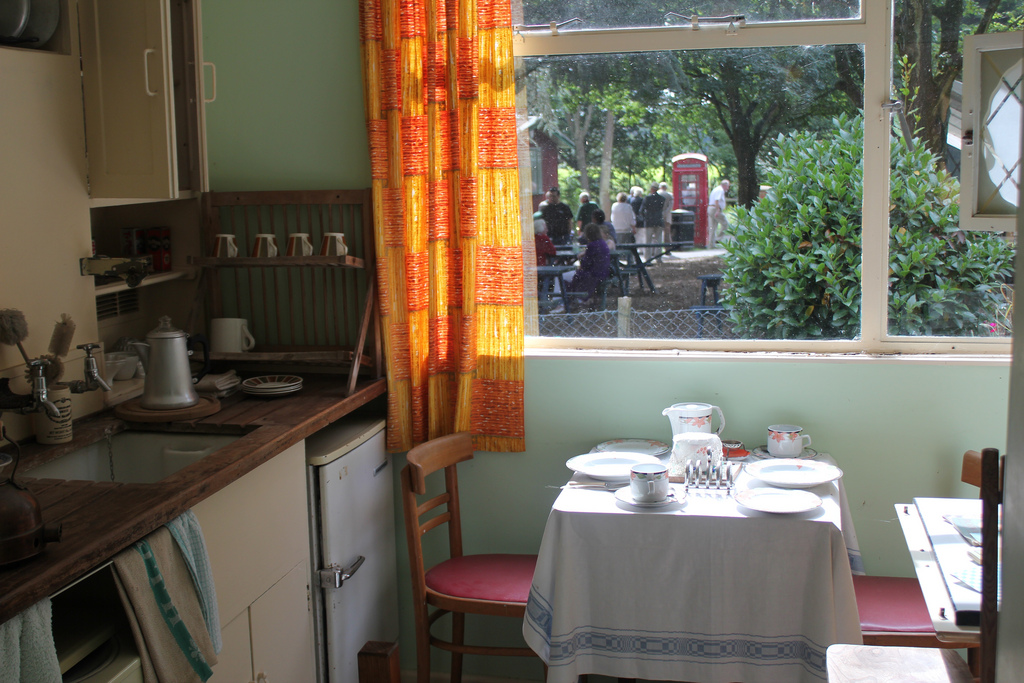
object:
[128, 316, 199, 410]
cup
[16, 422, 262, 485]
sink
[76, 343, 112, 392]
faucet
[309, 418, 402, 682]
fridge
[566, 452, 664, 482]
plate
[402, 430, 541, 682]
chair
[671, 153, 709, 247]
booth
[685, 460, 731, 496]
caddy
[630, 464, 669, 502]
cup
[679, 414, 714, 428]
pitcher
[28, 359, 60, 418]
faucets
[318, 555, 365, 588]
handle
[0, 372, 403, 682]
counter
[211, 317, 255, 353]
cup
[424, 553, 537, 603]
seat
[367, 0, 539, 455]
curtain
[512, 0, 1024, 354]
window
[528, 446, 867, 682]
table